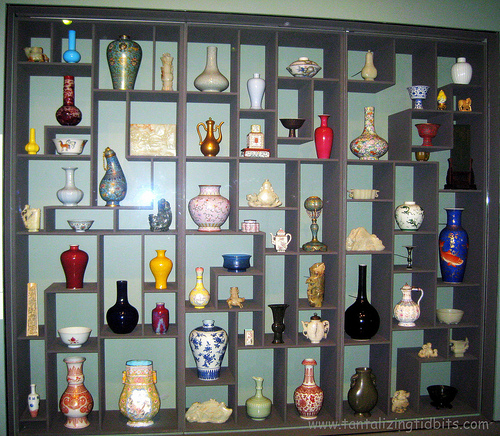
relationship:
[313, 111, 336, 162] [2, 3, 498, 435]
vase on top of cabinet